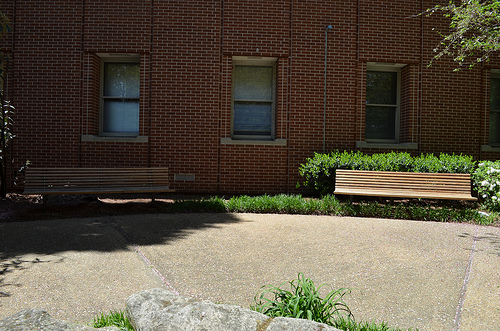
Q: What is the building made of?
A: Brick.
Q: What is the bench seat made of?
A: Wood.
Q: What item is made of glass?
A: Windows.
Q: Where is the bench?
A: Near grass.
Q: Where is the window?
A: Brick building.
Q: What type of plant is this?
A: Lush and green.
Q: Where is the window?
A: On the building.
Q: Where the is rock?
A: Near grass.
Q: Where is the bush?
A: Behind the bench.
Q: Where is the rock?
A: By the grass.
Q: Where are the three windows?
A: On the building.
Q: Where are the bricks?
A: Around the window.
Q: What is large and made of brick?
A: The building.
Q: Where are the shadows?
A: On the concrete.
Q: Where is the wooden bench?
A: Outside in the sun.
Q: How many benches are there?
A: Two.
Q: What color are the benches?
A: Brown.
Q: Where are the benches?
A: Beyond the sidewalk.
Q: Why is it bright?
A: The sun is shining.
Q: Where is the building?
A: Behind the benches.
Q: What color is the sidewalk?
A: Gray.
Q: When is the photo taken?
A: Daytime.